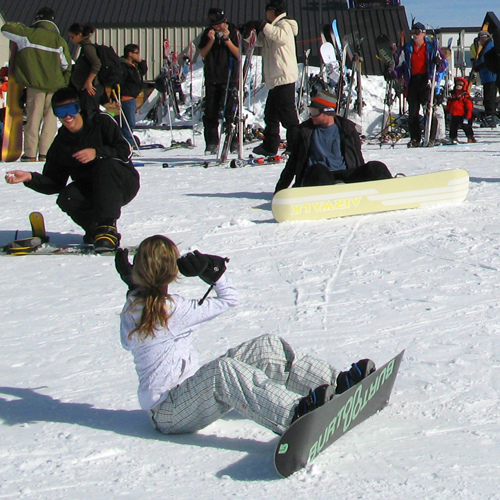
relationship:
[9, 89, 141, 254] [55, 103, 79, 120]
man wearing goggles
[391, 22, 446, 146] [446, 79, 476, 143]
parent has a child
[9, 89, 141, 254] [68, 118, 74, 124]
man has a smile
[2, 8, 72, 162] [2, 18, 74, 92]
man has a jacket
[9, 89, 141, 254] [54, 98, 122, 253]
man has on gear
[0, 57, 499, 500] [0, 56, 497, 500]
ground has snow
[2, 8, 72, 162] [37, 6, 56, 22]
man has a hat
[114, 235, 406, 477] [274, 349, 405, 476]
woman has a snowboard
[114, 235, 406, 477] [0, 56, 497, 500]
woman on snow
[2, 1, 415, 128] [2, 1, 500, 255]
building in background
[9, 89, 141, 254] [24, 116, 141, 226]
man wearing black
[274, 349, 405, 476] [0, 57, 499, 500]
snowboard on ground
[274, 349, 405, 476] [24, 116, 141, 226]
snowboard wearing black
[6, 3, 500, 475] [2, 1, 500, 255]
people are in background